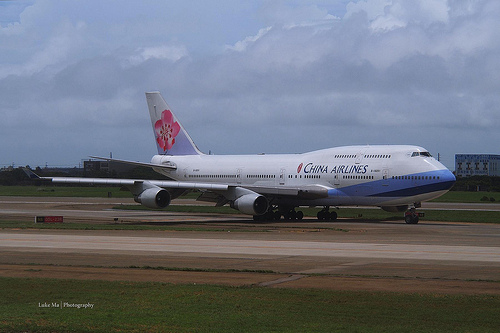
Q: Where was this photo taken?
A: On a runway.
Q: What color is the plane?
A: White and blue.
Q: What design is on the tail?
A: A pink flower.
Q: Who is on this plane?
A: People going to or from China.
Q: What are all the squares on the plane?
A: The windows.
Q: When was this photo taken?
A: During the day.